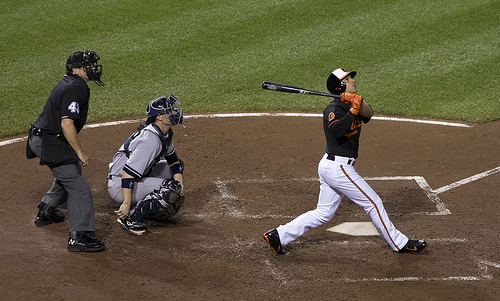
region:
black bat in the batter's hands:
[258, 77, 343, 100]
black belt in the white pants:
[322, 153, 357, 167]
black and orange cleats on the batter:
[261, 228, 429, 256]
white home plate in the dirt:
[323, 220, 380, 238]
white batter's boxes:
[213, 173, 493, 282]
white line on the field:
[433, 166, 499, 196]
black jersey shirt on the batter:
[321, 98, 361, 157]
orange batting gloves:
[338, 89, 365, 110]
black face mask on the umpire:
[79, 46, 106, 90]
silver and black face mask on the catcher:
[163, 92, 185, 128]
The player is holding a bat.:
[243, 65, 364, 102]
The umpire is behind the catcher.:
[28, 47, 184, 242]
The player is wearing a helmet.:
[333, 66, 367, 85]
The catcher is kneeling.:
[116, 90, 209, 241]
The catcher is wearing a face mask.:
[158, 94, 178, 124]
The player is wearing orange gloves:
[342, 88, 364, 107]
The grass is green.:
[136, 14, 498, 115]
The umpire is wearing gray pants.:
[26, 135, 110, 230]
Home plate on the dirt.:
[315, 191, 406, 248]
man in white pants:
[294, 66, 386, 233]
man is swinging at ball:
[261, 42, 391, 260]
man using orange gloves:
[313, 93, 382, 169]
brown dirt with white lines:
[236, 128, 283, 170]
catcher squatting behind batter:
[112, 93, 205, 248]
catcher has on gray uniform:
[106, 126, 176, 206]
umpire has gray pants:
[28, 129, 65, 207]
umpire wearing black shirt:
[29, 88, 91, 165]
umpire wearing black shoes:
[63, 226, 110, 261]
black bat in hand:
[260, 79, 357, 96]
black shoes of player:
[401, 241, 423, 251]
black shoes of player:
[264, 228, 286, 252]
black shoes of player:
[115, 217, 142, 234]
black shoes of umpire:
[68, 240, 105, 252]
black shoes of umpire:
[37, 208, 62, 219]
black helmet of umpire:
[151, 96, 183, 121]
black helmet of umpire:
[330, 65, 350, 92]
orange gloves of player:
[341, 94, 368, 105]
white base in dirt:
[327, 219, 384, 235]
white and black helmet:
[320, 59, 345, 94]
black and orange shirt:
[314, 92, 361, 162]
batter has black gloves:
[333, 84, 363, 106]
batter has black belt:
[310, 146, 360, 186]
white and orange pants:
[312, 159, 396, 263]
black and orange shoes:
[395, 237, 420, 259]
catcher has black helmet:
[135, 79, 170, 124]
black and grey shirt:
[95, 128, 165, 176]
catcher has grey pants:
[95, 169, 175, 209]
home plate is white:
[323, 212, 408, 263]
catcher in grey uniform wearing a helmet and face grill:
[103, 89, 190, 240]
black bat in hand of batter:
[256, 77, 362, 111]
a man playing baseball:
[258, 56, 410, 268]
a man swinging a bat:
[257, 56, 397, 194]